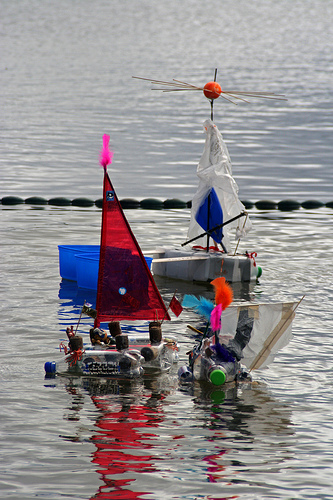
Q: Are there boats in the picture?
A: Yes, there is a boat.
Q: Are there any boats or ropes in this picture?
A: Yes, there is a boat.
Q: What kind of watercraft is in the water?
A: The watercraft is a boat.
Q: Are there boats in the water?
A: Yes, there is a boat in the water.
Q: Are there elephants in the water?
A: No, there is a boat in the water.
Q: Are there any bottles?
A: Yes, there is a bottle.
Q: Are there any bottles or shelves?
A: Yes, there is a bottle.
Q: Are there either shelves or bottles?
A: Yes, there is a bottle.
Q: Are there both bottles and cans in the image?
A: No, there is a bottle but no cans.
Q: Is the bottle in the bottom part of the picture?
A: Yes, the bottle is in the bottom of the image.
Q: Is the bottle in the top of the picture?
A: No, the bottle is in the bottom of the image.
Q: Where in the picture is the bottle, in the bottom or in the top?
A: The bottle is in the bottom of the image.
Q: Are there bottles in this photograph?
A: Yes, there is a bottle.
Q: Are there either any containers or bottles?
A: Yes, there is a bottle.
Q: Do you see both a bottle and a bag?
A: No, there is a bottle but no bags.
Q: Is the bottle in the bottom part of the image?
A: Yes, the bottle is in the bottom of the image.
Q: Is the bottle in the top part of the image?
A: No, the bottle is in the bottom of the image.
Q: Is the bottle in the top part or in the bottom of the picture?
A: The bottle is in the bottom of the image.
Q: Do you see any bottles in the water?
A: Yes, there is a bottle in the water.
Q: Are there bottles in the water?
A: Yes, there is a bottle in the water.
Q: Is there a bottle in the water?
A: Yes, there is a bottle in the water.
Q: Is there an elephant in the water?
A: No, there is a bottle in the water.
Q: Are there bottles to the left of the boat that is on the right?
A: Yes, there is a bottle to the left of the boat.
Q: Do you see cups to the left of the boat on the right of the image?
A: No, there is a bottle to the left of the boat.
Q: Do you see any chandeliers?
A: No, there are no chandeliers.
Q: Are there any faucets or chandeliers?
A: No, there are no chandeliers or faucets.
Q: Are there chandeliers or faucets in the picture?
A: No, there are no chandeliers or faucets.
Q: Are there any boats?
A: Yes, there is a boat.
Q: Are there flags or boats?
A: Yes, there is a boat.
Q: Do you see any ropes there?
A: No, there are no ropes.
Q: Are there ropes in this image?
A: No, there are no ropes.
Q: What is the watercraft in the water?
A: The watercraft is a boat.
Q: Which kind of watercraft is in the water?
A: The watercraft is a boat.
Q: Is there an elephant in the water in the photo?
A: No, there is a boat in the water.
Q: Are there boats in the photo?
A: Yes, there is a boat.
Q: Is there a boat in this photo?
A: Yes, there is a boat.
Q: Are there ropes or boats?
A: Yes, there is a boat.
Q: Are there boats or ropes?
A: Yes, there is a boat.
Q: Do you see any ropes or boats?
A: Yes, there is a boat.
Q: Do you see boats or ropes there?
A: Yes, there is a boat.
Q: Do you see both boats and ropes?
A: No, there is a boat but no ropes.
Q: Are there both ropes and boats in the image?
A: No, there is a boat but no ropes.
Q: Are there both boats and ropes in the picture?
A: No, there is a boat but no ropes.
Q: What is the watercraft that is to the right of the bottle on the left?
A: The watercraft is a boat.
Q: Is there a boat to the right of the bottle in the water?
A: Yes, there is a boat to the right of the bottle.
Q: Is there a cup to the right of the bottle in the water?
A: No, there is a boat to the right of the bottle.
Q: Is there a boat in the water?
A: Yes, there is a boat in the water.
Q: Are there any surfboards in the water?
A: No, there is a boat in the water.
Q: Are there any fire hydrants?
A: No, there are no fire hydrants.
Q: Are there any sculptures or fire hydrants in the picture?
A: No, there are no fire hydrants or sculptures.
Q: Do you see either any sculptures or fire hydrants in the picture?
A: No, there are no fire hydrants or sculptures.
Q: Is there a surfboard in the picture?
A: No, there are no surfboards.